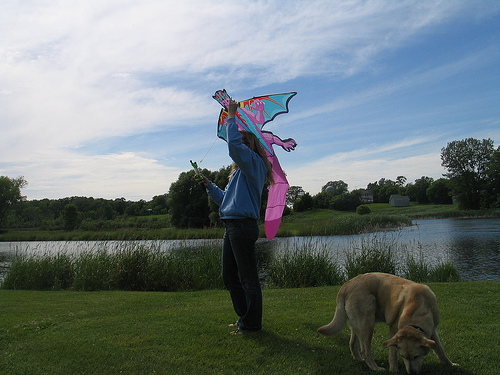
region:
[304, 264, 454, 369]
brown lab on grass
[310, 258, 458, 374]
dog sniffing the grass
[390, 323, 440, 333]
black collar on dog neck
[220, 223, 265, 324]
black pants on woman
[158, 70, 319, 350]
woman holding up kite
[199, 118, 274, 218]
blue sweatshirt on woman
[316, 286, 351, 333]
brown and tan tail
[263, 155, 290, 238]
pink tail of kite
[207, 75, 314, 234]
dragon shaped kite in hand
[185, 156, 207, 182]
handle of kite string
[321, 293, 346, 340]
The tail of the dog.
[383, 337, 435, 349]
The ears of the dog.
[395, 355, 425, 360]
The eyes of the dog.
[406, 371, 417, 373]
The nose of the dog.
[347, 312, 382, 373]
The back legs of the dog.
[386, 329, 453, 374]
The front legs of the dog.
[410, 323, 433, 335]
The collar the dog is wearing.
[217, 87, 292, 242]
The kite in the woman's hands.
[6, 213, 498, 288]
The water in the background.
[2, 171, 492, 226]
The trees in the distance.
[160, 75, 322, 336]
girl on the grass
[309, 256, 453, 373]
the dog beside the girl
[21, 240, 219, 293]
reeds beside the water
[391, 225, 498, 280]
the water is calm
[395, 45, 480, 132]
the sky is blue and clear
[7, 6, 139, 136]
clouds in the sky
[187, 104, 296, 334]
girl holding the kite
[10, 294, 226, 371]
the grass is trimmed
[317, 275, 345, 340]
tail of the dog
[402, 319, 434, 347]
collar on the dog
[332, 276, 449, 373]
the dog is brown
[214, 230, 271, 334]
the pants are black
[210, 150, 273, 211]
the sweater is blue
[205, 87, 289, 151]
the kite is blue in color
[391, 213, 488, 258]
water is in the background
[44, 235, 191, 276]
grass is on the riverbanks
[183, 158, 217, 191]
the woman is holding kite handle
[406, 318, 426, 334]
colar is on the dog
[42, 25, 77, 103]
clouds are in the sky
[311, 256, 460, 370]
the dog is sniffing at the grass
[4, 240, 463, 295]
The grass blades near the water.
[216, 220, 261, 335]
The pants the woman is wearing.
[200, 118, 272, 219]
The sweater the woman is wearing.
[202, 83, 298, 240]
The kite the woman is holding up.